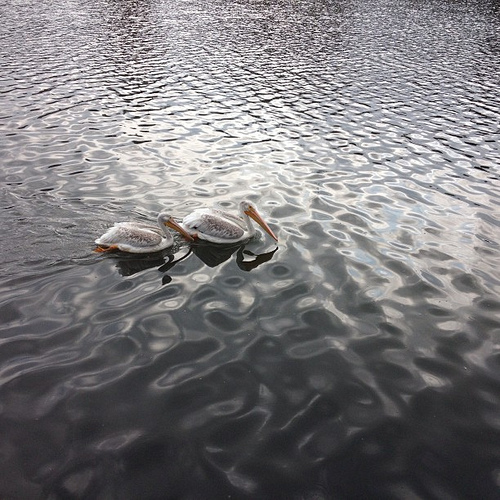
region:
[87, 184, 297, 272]
the ducks are two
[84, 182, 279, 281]
the ducks are floating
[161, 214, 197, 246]
the beak is long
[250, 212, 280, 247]
the beak is long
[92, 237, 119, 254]
the feet are orange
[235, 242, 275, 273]
shadow is on the water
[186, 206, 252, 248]
the feathers are black and white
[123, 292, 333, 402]
small riples are on the water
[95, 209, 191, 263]
the duck is small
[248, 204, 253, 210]
eye of the crane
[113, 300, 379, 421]
dark and wavy water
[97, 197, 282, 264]
two cranes floating on water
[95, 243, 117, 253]
leg of the crane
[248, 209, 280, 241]
long beak of the crane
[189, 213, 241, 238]
wings of crane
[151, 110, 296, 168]
light falling on water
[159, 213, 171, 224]
head of the crane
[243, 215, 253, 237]
neck of the crane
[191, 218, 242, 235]
white and brown spot on wings of crane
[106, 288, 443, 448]
the ripples in the water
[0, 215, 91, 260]
the disturbance in the water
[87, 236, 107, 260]
the foot paddeling in the water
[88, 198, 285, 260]
the birds swimming in the water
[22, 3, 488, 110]
the water glistening in the sun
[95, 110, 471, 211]
the glare of the sun off the water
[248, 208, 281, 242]
the orange beak of the bird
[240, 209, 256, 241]
the neck of the bird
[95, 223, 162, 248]
the wing of the bird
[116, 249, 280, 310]
the birds shadow on the top of the water